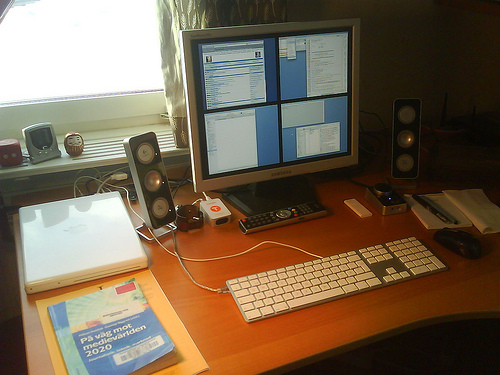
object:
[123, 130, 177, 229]
speaker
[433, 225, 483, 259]
computer mouse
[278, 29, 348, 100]
window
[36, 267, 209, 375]
folder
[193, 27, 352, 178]
computer screen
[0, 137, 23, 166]
window figuren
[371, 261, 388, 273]
silver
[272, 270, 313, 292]
white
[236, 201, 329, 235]
remote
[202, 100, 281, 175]
window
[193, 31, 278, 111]
window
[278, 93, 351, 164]
window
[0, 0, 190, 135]
window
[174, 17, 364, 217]
computer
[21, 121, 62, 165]
digital clock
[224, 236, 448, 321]
keyboard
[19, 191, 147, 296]
laptop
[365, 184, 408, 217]
camera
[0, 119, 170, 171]
window sill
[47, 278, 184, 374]
book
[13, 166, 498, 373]
desk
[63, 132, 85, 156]
figuren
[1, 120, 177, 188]
cile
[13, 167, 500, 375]
table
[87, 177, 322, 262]
wires